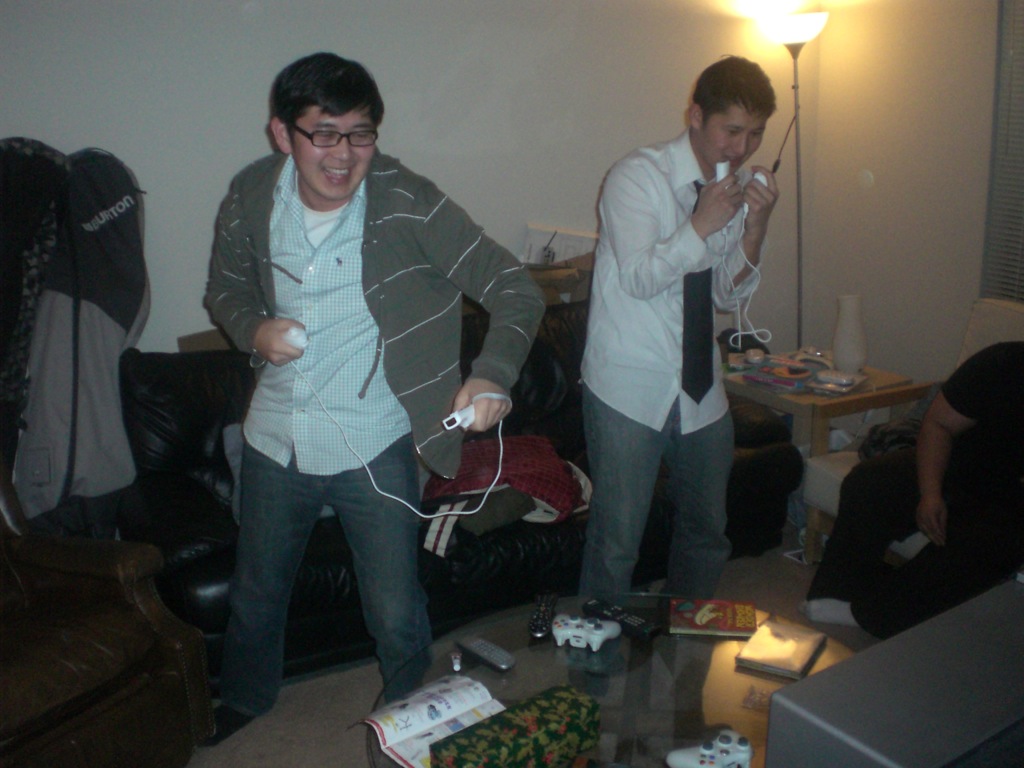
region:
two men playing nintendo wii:
[206, 10, 789, 555]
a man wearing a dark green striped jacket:
[217, 59, 534, 452]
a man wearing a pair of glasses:
[262, 50, 402, 218]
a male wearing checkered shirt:
[217, 34, 464, 502]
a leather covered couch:
[8, 506, 221, 766]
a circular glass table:
[337, 590, 850, 765]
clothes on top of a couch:
[382, 421, 614, 558]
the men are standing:
[201, 56, 781, 739]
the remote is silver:
[454, 632, 512, 670]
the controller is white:
[551, 609, 621, 651]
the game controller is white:
[667, 724, 750, 766]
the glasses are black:
[275, 116, 380, 152]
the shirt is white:
[579, 127, 764, 431]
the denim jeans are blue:
[577, 367, 732, 603]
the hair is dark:
[273, 48, 387, 148]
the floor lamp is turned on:
[760, 7, 827, 346]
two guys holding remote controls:
[196, 47, 795, 711]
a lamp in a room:
[759, 12, 846, 352]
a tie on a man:
[685, 173, 728, 418]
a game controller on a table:
[547, 609, 624, 654]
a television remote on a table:
[451, 614, 522, 687]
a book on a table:
[664, 594, 778, 643]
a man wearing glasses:
[282, 111, 390, 170]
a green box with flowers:
[421, 683, 618, 767]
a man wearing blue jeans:
[205, 420, 453, 734]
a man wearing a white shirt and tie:
[566, 53, 789, 443]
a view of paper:
[370, 623, 478, 745]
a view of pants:
[199, 511, 504, 673]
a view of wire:
[430, 464, 557, 554]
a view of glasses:
[262, 104, 395, 162]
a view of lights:
[743, 10, 870, 56]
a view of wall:
[125, 116, 274, 252]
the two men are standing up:
[197, 51, 774, 745]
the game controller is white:
[547, 610, 620, 652]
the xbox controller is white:
[667, 721, 751, 764]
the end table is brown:
[731, 337, 937, 563]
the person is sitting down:
[800, 335, 1022, 637]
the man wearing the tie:
[577, 54, 781, 694]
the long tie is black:
[680, 181, 716, 404]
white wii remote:
[443, 388, 502, 462]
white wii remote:
[706, 148, 757, 241]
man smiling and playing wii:
[188, 10, 542, 744]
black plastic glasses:
[277, 104, 392, 163]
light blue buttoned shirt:
[254, 158, 422, 500]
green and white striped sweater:
[187, 141, 541, 489]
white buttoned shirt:
[590, 139, 764, 446]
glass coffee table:
[368, 578, 880, 765]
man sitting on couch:
[808, 293, 1021, 622]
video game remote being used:
[433, 390, 507, 430]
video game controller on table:
[550, 607, 615, 652]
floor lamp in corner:
[750, 10, 821, 339]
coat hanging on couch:
[5, 146, 142, 535]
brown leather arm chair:
[0, 465, 222, 760]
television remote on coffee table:
[452, 629, 516, 671]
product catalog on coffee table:
[356, 668, 499, 760]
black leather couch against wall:
[108, 288, 802, 681]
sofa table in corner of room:
[721, 340, 949, 537]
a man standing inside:
[536, 57, 835, 478]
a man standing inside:
[158, 53, 541, 483]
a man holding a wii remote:
[615, 44, 803, 381]